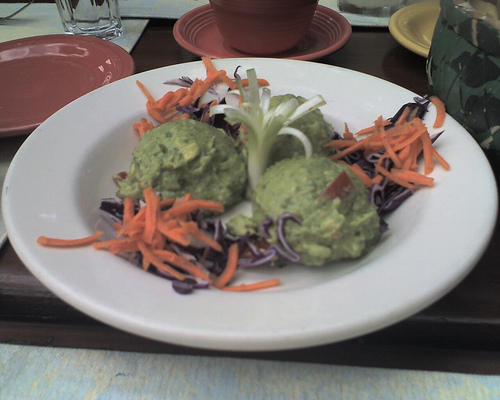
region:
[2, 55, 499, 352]
A white plate with food on it.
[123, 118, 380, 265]
Two sticky green balls of food in the middle of a plate.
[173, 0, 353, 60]
An orange saucer with a cup in the middle.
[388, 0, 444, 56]
A yellow plate.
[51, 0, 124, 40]
A clear glass up on the table.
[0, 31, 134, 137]
An empty orange plate.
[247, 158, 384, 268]
A lump of green on the right side of a plate.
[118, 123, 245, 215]
A green lumpy ball to the left of another.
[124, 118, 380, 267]
Two green lumpy balls on a plate of veggies.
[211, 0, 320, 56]
An orange bowl on an orange saucer.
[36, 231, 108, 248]
Small long strand of orange carrot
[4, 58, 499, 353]
Large white ceramic dish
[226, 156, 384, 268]
Ball of green chunky sauce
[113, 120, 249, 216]
small ball of green pasty sauce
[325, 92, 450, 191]
Pile of orange carrot strands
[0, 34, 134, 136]
Reddish ruddy ceramic plate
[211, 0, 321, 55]
Small reddish round dish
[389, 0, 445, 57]
Small round yellowish dish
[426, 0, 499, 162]
Large round greenish pot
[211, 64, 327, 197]
Large white vegetable sprout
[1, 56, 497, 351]
A white plate with vegetables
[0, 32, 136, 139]
An empty red plate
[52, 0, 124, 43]
The bottom half of a clear empty glass cup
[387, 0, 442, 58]
Part of an empty yellow plate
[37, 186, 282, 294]
Some shredded carrots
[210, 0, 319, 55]
The bottom half of a red bowl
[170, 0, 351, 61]
A red dish with a bowl on it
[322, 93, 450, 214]
A small portion of shredded cabbage and shredded carrots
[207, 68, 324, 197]
A vegetable cut to look like a flower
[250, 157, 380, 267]
A dollop of avocados mixed with other ingredients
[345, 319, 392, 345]
edge of a plate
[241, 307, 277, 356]
part of a plate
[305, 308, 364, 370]
part of a plate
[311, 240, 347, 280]
part of a fruit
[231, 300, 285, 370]
edge of a plate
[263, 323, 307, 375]
edge of a plate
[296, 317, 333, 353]
edge of a plate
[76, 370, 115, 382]
this is a table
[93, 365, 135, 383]
the table is white in color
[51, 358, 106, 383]
the table is wooden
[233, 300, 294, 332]
this is a plate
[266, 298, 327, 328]
the table is white in color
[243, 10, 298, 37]
this is a cup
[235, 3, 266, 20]
the cup is red in color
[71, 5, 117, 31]
this is a glass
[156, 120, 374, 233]
this is some food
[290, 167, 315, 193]
the food is green in color